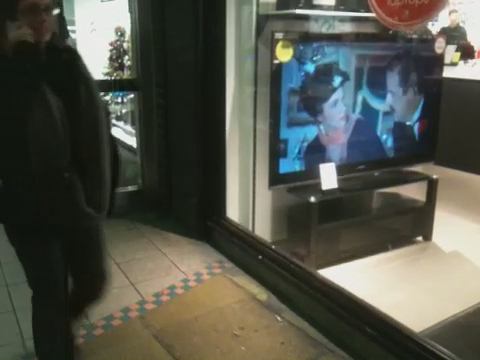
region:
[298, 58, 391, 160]
Mary Poppins showing on tv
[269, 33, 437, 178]
flat screen television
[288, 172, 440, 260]
black cabinet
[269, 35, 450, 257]
black cabinet with a flat screen tv sitting on top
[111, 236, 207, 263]
tan tile flooring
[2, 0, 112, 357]
person in glasses talking on the phone while walking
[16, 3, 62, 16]
glasses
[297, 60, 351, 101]
black hat on Mary Poppins' head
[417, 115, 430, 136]
red rose on lapel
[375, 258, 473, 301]
section of tan floor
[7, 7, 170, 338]
the man is walking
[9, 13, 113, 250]
man talking on the phone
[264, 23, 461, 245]
TV is turned on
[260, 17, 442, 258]
TV inside the store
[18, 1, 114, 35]
person is wearing eyeglasses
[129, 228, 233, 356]
the floor is tiled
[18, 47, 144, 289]
person is wearing a jacket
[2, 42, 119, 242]
the jacket is black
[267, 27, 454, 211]
the TV is flat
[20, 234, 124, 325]
the pants are black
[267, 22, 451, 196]
a flat screen television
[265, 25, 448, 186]
TV is turn on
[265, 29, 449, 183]
a yellow circle on upper left corner of TV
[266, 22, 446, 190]
frame of TV is black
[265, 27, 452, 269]
a television is on a small table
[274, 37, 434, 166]
a woman and a man in a TV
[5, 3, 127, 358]
a person is walking in the room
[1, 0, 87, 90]
person wears glasses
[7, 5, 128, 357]
person wears a winter coat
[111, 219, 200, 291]
part of the floor with tiles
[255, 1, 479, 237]
Mary Poppins on television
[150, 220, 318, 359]
the floor in front of the window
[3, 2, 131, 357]
A person standing outside the window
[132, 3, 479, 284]
A television in a window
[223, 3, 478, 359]
A storefront window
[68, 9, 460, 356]
Storefront windows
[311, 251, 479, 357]
The floor inside a storefront window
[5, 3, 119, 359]
A person standing outside a store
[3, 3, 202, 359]
A person exiting a store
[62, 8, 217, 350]
The entrance of a store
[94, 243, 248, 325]
blue and pink trim tile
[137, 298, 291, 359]
brown tile flooring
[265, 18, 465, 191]
flat screen TV on display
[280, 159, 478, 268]
black TV stand for a large flat screen TV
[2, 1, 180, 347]
person talking on cell phone while walking down side walk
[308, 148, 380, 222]
white price tag on TV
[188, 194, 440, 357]
black molding on outside of building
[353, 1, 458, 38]
bottom of red advertising sticker on window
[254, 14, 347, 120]
yellow sticker on top corner of TV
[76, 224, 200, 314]
beige tile flooring